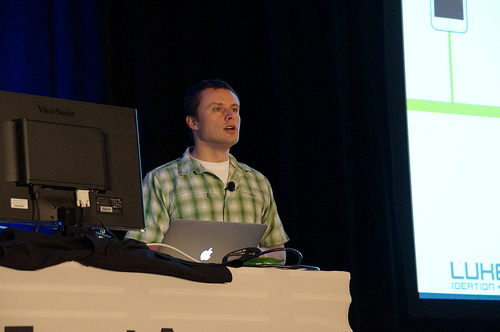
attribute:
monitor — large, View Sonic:
[0, 88, 146, 232]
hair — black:
[182, 68, 240, 119]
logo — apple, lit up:
[196, 243, 213, 262]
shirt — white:
[180, 145, 242, 190]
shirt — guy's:
[124, 151, 289, 262]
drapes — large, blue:
[1, 1, 118, 103]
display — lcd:
[387, 0, 498, 303]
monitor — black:
[0, 81, 167, 266]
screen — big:
[392, 7, 498, 309]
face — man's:
[178, 80, 245, 147]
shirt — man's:
[133, 146, 300, 246]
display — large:
[390, 16, 496, 308]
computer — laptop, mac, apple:
[162, 217, 264, 261]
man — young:
[196, 89, 253, 146]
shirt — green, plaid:
[145, 155, 237, 218]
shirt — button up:
[141, 180, 273, 228]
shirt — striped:
[121, 144, 292, 249]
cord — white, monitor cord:
[15, 198, 167, 270]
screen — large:
[351, 3, 484, 328]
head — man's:
[181, 80, 241, 148]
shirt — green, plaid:
[140, 147, 288, 265]